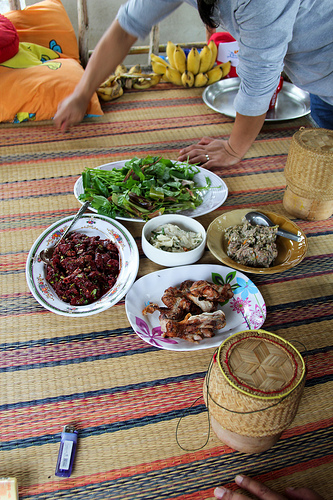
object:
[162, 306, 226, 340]
chicken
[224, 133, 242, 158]
wrist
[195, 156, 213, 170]
fingers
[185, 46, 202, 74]
bananas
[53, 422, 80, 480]
lighter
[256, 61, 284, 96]
elbow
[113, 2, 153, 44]
elbow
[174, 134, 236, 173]
hand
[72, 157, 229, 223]
plate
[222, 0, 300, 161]
arm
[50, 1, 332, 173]
person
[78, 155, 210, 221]
food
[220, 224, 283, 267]
food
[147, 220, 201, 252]
food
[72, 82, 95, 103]
wrist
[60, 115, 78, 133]
thumb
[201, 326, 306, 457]
basket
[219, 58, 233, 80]
bananas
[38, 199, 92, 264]
spoon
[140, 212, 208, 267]
bowl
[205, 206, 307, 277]
bowl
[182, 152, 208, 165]
fingers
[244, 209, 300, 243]
spoon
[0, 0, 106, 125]
pillow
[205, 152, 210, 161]
silver ring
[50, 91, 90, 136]
hand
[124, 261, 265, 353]
bowl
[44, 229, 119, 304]
food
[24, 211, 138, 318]
bowl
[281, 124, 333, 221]
basket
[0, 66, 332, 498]
table